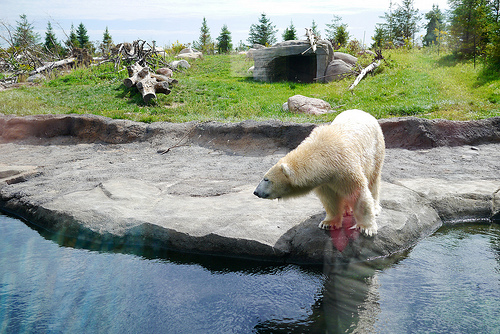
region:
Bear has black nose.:
[253, 186, 264, 204]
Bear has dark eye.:
[258, 173, 273, 193]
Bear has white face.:
[251, 175, 270, 200]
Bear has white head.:
[264, 161, 287, 172]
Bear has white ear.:
[274, 165, 292, 175]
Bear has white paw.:
[349, 202, 396, 254]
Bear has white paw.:
[320, 205, 345, 249]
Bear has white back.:
[331, 105, 359, 151]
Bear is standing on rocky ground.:
[303, 188, 385, 260]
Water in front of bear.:
[156, 268, 256, 333]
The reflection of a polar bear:
[251, 267, 408, 330]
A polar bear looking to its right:
[248, 104, 398, 236]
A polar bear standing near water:
[253, 108, 418, 318]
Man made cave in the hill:
[243, 27, 365, 89]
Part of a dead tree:
[109, 41, 176, 106]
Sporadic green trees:
[379, 6, 445, 52]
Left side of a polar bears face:
[255, 157, 300, 203]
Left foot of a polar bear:
[353, 213, 380, 238]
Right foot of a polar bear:
[313, 207, 348, 233]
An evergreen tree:
[215, 19, 239, 51]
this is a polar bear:
[247, 80, 451, 297]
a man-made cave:
[223, 23, 380, 92]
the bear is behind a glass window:
[46, 16, 492, 280]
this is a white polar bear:
[193, 66, 492, 282]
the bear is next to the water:
[217, 83, 450, 283]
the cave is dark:
[243, 45, 400, 117]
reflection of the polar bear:
[255, 277, 380, 332]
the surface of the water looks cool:
[2, 220, 497, 328]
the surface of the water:
[4, 206, 498, 332]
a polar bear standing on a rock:
[210, 69, 453, 302]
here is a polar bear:
[230, 85, 465, 235]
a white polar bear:
[245, 90, 420, 260]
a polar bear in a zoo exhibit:
[245, 105, 455, 280]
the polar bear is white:
[235, 80, 410, 240]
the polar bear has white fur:
[236, 77, 429, 263]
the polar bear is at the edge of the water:
[247, 87, 446, 263]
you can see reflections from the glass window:
[2, 0, 489, 327]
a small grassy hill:
[25, 33, 497, 120]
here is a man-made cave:
[236, 25, 359, 95]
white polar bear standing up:
[253, 107, 388, 253]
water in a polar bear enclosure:
[4, 198, 499, 330]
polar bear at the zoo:
[250, 108, 386, 242]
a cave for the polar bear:
[246, 34, 361, 81]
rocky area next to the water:
[2, 108, 491, 263]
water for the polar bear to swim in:
[0, 198, 498, 332]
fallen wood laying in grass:
[10, 44, 181, 108]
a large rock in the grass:
[284, 92, 333, 119]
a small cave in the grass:
[249, 37, 359, 86]